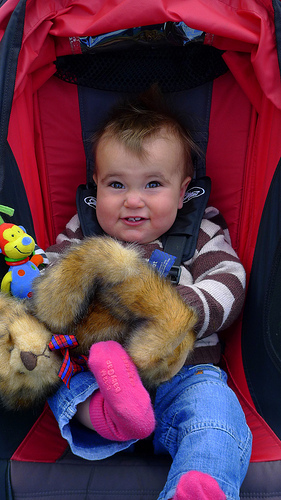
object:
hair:
[91, 105, 194, 181]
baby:
[46, 101, 253, 498]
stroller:
[0, 0, 281, 500]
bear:
[0, 233, 198, 412]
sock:
[87, 339, 156, 440]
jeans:
[47, 362, 253, 499]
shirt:
[44, 205, 246, 366]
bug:
[0, 222, 46, 302]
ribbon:
[48, 335, 91, 390]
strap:
[158, 175, 212, 286]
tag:
[148, 248, 177, 279]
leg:
[154, 361, 252, 500]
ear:
[178, 177, 192, 209]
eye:
[145, 180, 164, 189]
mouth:
[118, 215, 150, 225]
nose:
[123, 188, 145, 210]